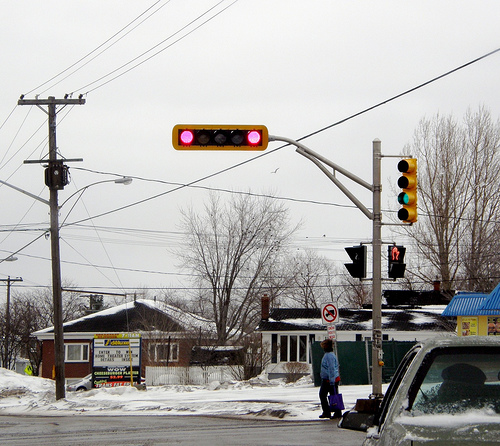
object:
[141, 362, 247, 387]
fence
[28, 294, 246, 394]
building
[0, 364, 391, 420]
snow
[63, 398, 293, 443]
ground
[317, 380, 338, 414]
pants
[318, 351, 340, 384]
jacket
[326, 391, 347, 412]
bag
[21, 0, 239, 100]
cables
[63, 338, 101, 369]
window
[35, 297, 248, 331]
snow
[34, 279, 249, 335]
roof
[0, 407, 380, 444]
street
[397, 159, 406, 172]
light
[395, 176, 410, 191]
light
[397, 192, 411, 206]
light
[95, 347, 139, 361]
lettering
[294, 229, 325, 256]
birds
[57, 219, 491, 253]
lines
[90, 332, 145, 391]
sign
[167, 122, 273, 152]
light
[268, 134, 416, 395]
post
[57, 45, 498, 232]
lines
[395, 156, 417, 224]
light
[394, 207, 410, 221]
light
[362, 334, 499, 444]
car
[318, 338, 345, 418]
person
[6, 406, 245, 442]
road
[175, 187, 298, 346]
tree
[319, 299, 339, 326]
sign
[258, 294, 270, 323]
chimney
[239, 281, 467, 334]
roof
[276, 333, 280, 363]
lines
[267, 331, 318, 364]
window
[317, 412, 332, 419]
foot